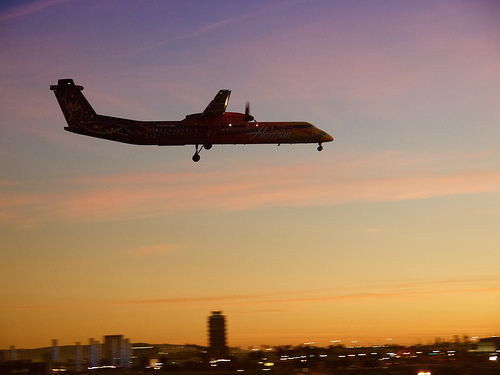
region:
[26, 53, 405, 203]
Propeller driven airline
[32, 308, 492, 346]
city skyline in the background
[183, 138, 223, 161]
lowered rear landing gear of plane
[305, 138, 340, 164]
lowered front landing gear of plane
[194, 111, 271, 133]
propeller engine under wing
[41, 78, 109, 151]
Tail of the airplane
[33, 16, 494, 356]
Purple pink and yellow sunset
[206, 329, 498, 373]
City street lights illuminated in the background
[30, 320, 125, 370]
White skyscrapers in the background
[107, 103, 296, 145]
Orange red and blue fuselage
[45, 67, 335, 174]
plane flying in air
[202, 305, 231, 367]
communication tower on horizon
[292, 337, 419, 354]
street lamps on horizon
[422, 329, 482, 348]
trees on horizon line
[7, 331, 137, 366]
building with pillars in background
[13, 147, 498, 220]
hazy clouds in sky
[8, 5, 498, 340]
blue, pink, orange and purple sky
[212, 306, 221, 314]
red light atop tower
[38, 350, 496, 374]
building lights along horizon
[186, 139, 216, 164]
back wheels on plane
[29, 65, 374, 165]
Plane flying through the sky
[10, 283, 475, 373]
City Skyline in background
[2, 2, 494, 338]
The sun is setting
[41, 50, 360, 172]
Plane is casting a silhouette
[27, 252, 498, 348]
The bottom of the sky is yellow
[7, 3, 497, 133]
The top of the sky is purple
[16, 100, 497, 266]
Soft pink clouds in sky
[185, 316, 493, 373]
Lights are on in the city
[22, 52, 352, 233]
There is one plane in the sky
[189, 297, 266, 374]
There is one very tall building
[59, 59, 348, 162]
AIRLINER COMING IN FOR LANDING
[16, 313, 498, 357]
CITY SKYLINE IN BACKGROUND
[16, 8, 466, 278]
BLUE, PINK, AND YELLOW SUNSET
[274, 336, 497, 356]
STREET LIGHTS ILLUMINATED IN CITY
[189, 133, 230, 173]
REAR LANDING GEAR OF PLANE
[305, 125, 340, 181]
FRONT LANDING GEAR OF PLANE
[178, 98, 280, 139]
TURBO PROP ENGINE UNDER WING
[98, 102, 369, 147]
BLUE YELLOW AND RED FUSELAGE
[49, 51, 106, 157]
TAIL OF DESCENDING PLANE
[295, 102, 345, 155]
COCKPIT OF DESCENDING PLANE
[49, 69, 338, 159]
colorful airplane coming in for a landing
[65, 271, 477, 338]
orange glow of sunset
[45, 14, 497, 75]
purple blue sky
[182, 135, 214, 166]
landing gear in the down position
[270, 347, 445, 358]
line of street lights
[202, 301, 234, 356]
tall concrete building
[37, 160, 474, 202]
pink clouds in sky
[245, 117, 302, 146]
Horizon written on plane in white letters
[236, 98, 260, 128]
propellor in motion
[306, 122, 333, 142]
blue stripe on nose of plane